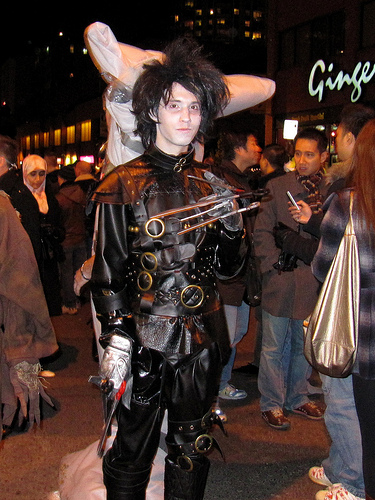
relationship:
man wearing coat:
[252, 129, 331, 429] [252, 170, 330, 320]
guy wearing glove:
[86, 39, 251, 500] [97, 334, 133, 411]